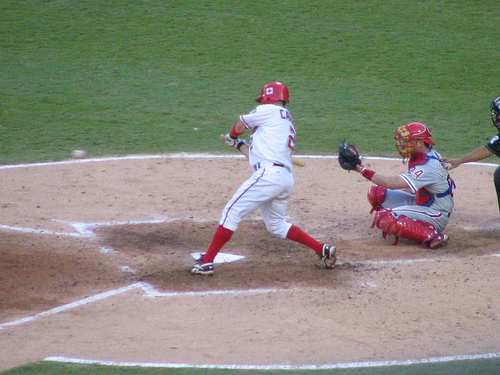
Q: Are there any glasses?
A: No, there are no glasses.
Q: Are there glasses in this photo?
A: No, there are no glasses.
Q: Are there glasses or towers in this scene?
A: No, there are no glasses or towers.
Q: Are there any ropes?
A: No, there are no ropes.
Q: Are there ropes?
A: No, there are no ropes.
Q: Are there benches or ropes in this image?
A: No, there are no ropes or benches.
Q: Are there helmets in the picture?
A: Yes, there is a helmet.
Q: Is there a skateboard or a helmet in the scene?
A: Yes, there is a helmet.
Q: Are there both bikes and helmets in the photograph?
A: No, there is a helmet but no bikes.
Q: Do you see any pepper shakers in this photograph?
A: No, there are no pepper shakers.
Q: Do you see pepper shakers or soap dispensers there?
A: No, there are no pepper shakers or soap dispensers.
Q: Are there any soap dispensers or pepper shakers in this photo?
A: No, there are no pepper shakers or soap dispensers.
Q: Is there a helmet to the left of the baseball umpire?
A: Yes, there is a helmet to the left of the umpire.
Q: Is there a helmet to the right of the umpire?
A: No, the helmet is to the left of the umpire.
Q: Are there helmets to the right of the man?
A: Yes, there is a helmet to the right of the man.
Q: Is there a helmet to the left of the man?
A: No, the helmet is to the right of the man.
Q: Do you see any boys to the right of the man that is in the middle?
A: No, there is a helmet to the right of the man.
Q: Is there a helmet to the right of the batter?
A: Yes, there is a helmet to the right of the batter.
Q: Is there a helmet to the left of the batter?
A: No, the helmet is to the right of the batter.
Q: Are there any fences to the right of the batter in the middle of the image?
A: No, there is a helmet to the right of the batter.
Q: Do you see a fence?
A: No, there are no fences.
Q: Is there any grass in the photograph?
A: Yes, there is grass.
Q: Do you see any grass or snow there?
A: Yes, there is grass.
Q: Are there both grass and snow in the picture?
A: No, there is grass but no snow.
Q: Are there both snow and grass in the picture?
A: No, there is grass but no snow.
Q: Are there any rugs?
A: No, there are no rugs.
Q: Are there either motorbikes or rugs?
A: No, there are no rugs or motorbikes.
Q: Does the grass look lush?
A: Yes, the grass is lush.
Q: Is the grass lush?
A: Yes, the grass is lush.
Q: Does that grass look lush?
A: Yes, the grass is lush.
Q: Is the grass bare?
A: No, the grass is lush.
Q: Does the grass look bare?
A: No, the grass is lush.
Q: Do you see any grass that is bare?
A: No, there is grass but it is lush.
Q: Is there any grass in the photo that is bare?
A: No, there is grass but it is lush.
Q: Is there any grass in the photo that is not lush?
A: No, there is grass but it is lush.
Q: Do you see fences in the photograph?
A: No, there are no fences.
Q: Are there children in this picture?
A: No, there are no children.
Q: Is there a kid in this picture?
A: No, there are no children.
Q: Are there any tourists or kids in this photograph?
A: No, there are no kids or tourists.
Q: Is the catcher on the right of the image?
A: Yes, the catcher is on the right of the image.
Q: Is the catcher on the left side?
A: No, the catcher is on the right of the image.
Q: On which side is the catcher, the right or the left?
A: The catcher is on the right of the image.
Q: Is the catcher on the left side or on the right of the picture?
A: The catcher is on the right of the image.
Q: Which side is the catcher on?
A: The catcher is on the right of the image.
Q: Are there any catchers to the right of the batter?
A: Yes, there is a catcher to the right of the batter.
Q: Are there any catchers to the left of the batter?
A: No, the catcher is to the right of the batter.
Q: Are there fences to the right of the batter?
A: No, there is a catcher to the right of the batter.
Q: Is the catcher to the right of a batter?
A: Yes, the catcher is to the right of a batter.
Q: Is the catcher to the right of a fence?
A: No, the catcher is to the right of a batter.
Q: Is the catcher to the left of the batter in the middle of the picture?
A: No, the catcher is to the right of the batter.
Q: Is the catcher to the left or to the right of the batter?
A: The catcher is to the right of the batter.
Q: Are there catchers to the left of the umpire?
A: Yes, there is a catcher to the left of the umpire.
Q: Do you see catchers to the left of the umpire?
A: Yes, there is a catcher to the left of the umpire.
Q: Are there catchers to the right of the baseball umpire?
A: No, the catcher is to the left of the umpire.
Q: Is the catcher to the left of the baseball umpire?
A: Yes, the catcher is to the left of the umpire.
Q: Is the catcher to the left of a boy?
A: No, the catcher is to the left of the umpire.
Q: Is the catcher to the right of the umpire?
A: No, the catcher is to the left of the umpire.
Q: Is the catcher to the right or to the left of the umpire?
A: The catcher is to the left of the umpire.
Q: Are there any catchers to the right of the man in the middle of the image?
A: Yes, there is a catcher to the right of the man.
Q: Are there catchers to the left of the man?
A: No, the catcher is to the right of the man.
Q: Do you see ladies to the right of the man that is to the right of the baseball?
A: No, there is a catcher to the right of the man.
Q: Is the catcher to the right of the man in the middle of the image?
A: Yes, the catcher is to the right of the man.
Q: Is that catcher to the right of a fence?
A: No, the catcher is to the right of the man.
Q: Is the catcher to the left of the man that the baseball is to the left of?
A: No, the catcher is to the right of the man.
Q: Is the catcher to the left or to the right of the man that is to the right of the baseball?
A: The catcher is to the right of the man.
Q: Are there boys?
A: No, there are no boys.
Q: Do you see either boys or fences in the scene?
A: No, there are no boys or fences.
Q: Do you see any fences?
A: No, there are no fences.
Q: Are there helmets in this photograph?
A: Yes, there is a helmet.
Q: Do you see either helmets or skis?
A: Yes, there is a helmet.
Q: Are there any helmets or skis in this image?
A: Yes, there is a helmet.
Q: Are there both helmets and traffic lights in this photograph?
A: No, there is a helmet but no traffic lights.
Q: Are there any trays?
A: No, there are no trays.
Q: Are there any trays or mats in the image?
A: No, there are no trays or mats.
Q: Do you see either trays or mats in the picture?
A: No, there are no trays or mats.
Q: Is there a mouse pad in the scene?
A: No, there are no mouse pads.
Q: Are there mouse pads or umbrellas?
A: No, there are no mouse pads or umbrellas.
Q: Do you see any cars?
A: No, there are no cars.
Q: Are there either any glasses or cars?
A: No, there are no cars or glasses.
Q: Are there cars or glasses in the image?
A: No, there are no cars or glasses.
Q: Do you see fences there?
A: No, there are no fences.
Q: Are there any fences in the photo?
A: No, there are no fences.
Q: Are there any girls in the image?
A: No, there are no girls.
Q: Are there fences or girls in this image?
A: No, there are no girls or fences.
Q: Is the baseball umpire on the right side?
A: Yes, the umpire is on the right of the image.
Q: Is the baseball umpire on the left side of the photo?
A: No, the umpire is on the right of the image.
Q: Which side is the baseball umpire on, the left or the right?
A: The umpire is on the right of the image.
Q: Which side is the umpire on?
A: The umpire is on the right of the image.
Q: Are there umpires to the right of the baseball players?
A: Yes, there is an umpire to the right of the baseball players.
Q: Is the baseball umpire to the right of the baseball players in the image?
A: Yes, the umpire is to the right of the baseball players.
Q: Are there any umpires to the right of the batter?
A: Yes, there is an umpire to the right of the batter.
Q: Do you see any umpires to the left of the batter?
A: No, the umpire is to the right of the batter.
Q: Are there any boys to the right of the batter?
A: No, there is an umpire to the right of the batter.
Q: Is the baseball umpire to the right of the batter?
A: Yes, the umpire is to the right of the batter.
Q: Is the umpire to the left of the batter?
A: No, the umpire is to the right of the batter.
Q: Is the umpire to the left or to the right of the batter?
A: The umpire is to the right of the batter.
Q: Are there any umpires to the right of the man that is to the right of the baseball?
A: Yes, there is an umpire to the right of the man.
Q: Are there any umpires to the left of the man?
A: No, the umpire is to the right of the man.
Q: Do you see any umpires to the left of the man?
A: No, the umpire is to the right of the man.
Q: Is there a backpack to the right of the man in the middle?
A: No, there is an umpire to the right of the man.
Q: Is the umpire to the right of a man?
A: Yes, the umpire is to the right of a man.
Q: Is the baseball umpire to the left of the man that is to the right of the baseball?
A: No, the umpire is to the right of the man.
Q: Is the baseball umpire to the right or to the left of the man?
A: The umpire is to the right of the man.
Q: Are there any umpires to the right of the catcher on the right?
A: Yes, there is an umpire to the right of the catcher.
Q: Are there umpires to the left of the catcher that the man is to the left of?
A: No, the umpire is to the right of the catcher.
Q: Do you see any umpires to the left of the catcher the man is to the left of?
A: No, the umpire is to the right of the catcher.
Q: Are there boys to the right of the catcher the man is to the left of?
A: No, there is an umpire to the right of the catcher.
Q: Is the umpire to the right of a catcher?
A: Yes, the umpire is to the right of a catcher.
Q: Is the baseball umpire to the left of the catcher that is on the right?
A: No, the umpire is to the right of the catcher.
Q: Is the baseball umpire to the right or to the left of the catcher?
A: The umpire is to the right of the catcher.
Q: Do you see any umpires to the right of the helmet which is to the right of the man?
A: Yes, there is an umpire to the right of the helmet.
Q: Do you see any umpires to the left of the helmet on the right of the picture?
A: No, the umpire is to the right of the helmet.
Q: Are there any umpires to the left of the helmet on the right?
A: No, the umpire is to the right of the helmet.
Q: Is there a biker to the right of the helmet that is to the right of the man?
A: No, there is an umpire to the right of the helmet.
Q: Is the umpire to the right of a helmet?
A: Yes, the umpire is to the right of a helmet.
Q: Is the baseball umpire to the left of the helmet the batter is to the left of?
A: No, the umpire is to the right of the helmet.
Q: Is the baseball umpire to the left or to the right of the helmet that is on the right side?
A: The umpire is to the right of the helmet.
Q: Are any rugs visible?
A: No, there are no rugs.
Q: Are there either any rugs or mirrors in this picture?
A: No, there are no rugs or mirrors.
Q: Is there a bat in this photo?
A: Yes, there is a bat.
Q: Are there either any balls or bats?
A: Yes, there is a bat.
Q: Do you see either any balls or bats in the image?
A: Yes, there is a bat.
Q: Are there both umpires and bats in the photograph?
A: Yes, there are both a bat and an umpire.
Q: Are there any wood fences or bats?
A: Yes, there is a wood bat.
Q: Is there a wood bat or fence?
A: Yes, there is a wood bat.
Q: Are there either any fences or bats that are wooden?
A: Yes, the bat is wooden.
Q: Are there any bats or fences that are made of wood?
A: Yes, the bat is made of wood.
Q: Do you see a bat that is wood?
A: Yes, there is a wood bat.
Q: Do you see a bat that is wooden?
A: Yes, there is a bat that is wooden.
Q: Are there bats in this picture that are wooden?
A: Yes, there is a bat that is wooden.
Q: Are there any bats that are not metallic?
A: Yes, there is a wooden bat.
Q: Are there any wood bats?
A: Yes, there is a bat that is made of wood.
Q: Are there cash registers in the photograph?
A: No, there are no cash registers.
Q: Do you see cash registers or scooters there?
A: No, there are no cash registers or scooters.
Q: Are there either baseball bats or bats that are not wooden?
A: No, there is a bat but it is wooden.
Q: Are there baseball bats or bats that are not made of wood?
A: No, there is a bat but it is made of wood.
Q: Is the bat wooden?
A: Yes, the bat is wooden.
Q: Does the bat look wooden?
A: Yes, the bat is wooden.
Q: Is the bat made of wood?
A: Yes, the bat is made of wood.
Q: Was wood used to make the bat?
A: Yes, the bat is made of wood.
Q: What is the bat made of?
A: The bat is made of wood.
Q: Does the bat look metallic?
A: No, the bat is wooden.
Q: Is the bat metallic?
A: No, the bat is wooden.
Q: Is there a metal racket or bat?
A: No, there is a bat but it is wooden.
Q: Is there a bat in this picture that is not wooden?
A: No, there is a bat but it is wooden.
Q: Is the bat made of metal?
A: No, the bat is made of wood.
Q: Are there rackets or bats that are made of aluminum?
A: No, there is a bat but it is made of wood.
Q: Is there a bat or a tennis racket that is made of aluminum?
A: No, there is a bat but it is made of wood.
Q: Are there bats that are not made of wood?
A: No, there is a bat but it is made of wood.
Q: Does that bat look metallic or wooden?
A: The bat is wooden.